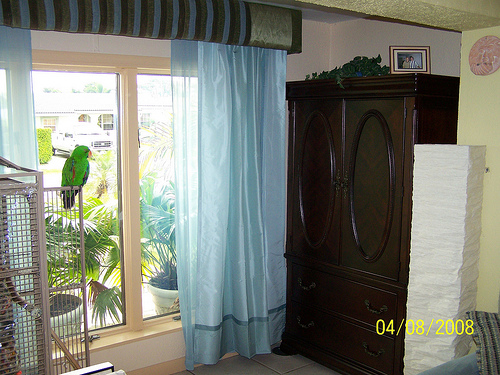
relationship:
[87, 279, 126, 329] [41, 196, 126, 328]
piece of greenery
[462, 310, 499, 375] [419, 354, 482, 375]
pillow on top of sofa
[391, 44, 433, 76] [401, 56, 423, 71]
photo of a couple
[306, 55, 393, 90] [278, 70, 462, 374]
plant on top of dresser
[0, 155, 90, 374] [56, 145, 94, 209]
cage for bird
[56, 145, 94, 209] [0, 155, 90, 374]
bird sitting on top of cage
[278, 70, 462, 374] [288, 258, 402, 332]
dresser has drawer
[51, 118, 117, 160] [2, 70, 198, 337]
vehicle parked outside